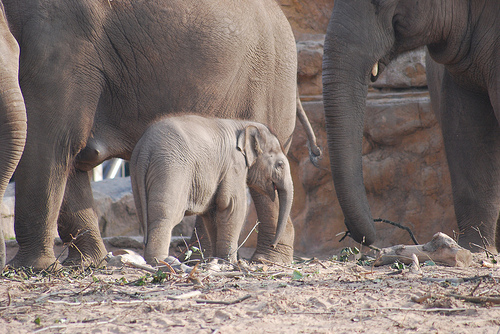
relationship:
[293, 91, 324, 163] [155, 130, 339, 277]
tail on elephant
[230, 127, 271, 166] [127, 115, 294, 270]
ear on elephant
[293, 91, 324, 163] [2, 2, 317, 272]
tail on elephant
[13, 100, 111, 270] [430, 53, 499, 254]
legs on elephant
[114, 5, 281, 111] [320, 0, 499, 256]
skin on elephant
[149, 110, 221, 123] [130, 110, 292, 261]
hair on elephant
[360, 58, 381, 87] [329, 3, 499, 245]
tusk on elephant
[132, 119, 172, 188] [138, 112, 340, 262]
behind on elephant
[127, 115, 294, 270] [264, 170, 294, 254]
elephant has elephant's trunk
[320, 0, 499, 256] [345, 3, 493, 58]
elephant has head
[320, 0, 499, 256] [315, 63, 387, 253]
elephant has trunk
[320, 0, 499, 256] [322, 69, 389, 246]
elephant has trunk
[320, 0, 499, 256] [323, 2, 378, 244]
elephant has trunk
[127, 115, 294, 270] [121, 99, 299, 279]
elephant has trunk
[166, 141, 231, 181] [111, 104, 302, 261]
dirt on elephant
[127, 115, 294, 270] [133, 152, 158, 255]
elephant has tail